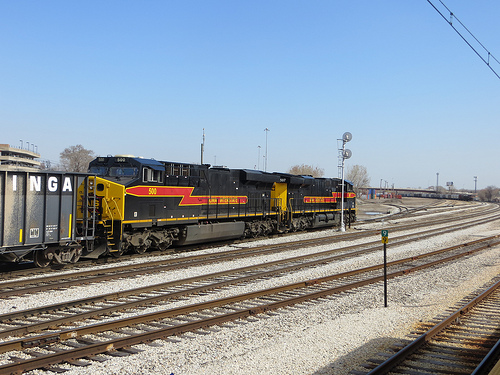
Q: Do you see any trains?
A: Yes, there is a train.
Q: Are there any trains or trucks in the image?
A: Yes, there is a train.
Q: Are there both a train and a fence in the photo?
A: No, there is a train but no fences.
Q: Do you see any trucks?
A: No, there are no trucks.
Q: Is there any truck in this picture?
A: No, there are no trucks.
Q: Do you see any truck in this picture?
A: No, there are no trucks.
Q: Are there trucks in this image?
A: No, there are no trucks.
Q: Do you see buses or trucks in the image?
A: No, there are no trucks or buses.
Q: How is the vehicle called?
A: The vehicle is a train.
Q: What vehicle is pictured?
A: The vehicle is a train.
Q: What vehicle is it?
A: The vehicle is a train.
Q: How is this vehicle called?
A: This is a train.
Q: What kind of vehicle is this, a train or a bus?
A: This is a train.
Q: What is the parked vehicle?
A: The vehicle is a train.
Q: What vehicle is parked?
A: The vehicle is a train.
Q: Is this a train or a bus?
A: This is a train.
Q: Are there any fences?
A: No, there are no fences.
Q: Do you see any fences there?
A: No, there are no fences.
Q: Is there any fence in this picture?
A: No, there are no fences.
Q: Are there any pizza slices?
A: No, there are no pizza slices.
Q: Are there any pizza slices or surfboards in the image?
A: No, there are no pizza slices or surfboards.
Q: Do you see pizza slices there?
A: No, there are no pizza slices.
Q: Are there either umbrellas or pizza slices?
A: No, there are no pizza slices or umbrellas.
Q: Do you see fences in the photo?
A: No, there are no fences.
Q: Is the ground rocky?
A: Yes, the ground is rocky.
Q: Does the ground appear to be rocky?
A: Yes, the ground is rocky.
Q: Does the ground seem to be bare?
A: No, the ground is rocky.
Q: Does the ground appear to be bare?
A: No, the ground is rocky.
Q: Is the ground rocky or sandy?
A: The ground is rocky.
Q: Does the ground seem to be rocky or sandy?
A: The ground is rocky.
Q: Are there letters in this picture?
A: Yes, there are letters.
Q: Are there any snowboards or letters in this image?
A: Yes, there are letters.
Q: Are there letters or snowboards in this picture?
A: Yes, there are letters.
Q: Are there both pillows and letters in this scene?
A: No, there are letters but no pillows.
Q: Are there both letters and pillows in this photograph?
A: No, there are letters but no pillows.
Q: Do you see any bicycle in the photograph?
A: No, there are no bicycles.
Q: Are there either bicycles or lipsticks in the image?
A: No, there are no bicycles or lipsticks.